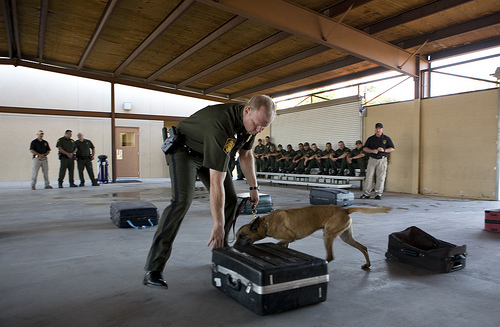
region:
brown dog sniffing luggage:
[249, 212, 365, 270]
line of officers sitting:
[265, 137, 417, 191]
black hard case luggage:
[233, 225, 333, 317]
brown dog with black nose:
[223, 183, 377, 292]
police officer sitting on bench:
[346, 137, 367, 174]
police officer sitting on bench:
[331, 140, 350, 173]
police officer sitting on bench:
[317, 142, 335, 173]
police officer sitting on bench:
[302, 142, 322, 173]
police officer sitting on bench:
[293, 141, 312, 172]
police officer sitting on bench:
[289, 142, 303, 174]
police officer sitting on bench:
[276, 142, 295, 171]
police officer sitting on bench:
[267, 140, 288, 169]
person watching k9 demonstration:
[358, 120, 393, 199]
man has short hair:
[231, 97, 318, 139]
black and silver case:
[203, 262, 335, 323]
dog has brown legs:
[294, 208, 371, 273]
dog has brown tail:
[340, 197, 385, 229]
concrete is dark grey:
[56, 247, 154, 323]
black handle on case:
[208, 262, 274, 317]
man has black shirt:
[186, 112, 238, 153]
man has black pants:
[146, 156, 200, 313]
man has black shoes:
[136, 271, 173, 289]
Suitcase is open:
[386, 212, 472, 277]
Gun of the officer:
[157, 124, 182, 156]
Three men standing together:
[21, 121, 96, 186]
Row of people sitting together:
[279, 136, 350, 171]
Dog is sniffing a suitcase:
[235, 205, 386, 273]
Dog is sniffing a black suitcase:
[229, 202, 384, 309]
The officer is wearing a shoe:
[129, 232, 179, 299]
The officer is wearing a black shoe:
[136, 247, 178, 295]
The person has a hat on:
[368, 120, 386, 140]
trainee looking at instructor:
[352, 138, 368, 174]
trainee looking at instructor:
[334, 138, 349, 167]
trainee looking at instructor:
[320, 137, 333, 168]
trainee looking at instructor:
[310, 140, 321, 166]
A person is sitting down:
[349, 130, 376, 180]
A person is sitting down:
[326, 134, 356, 180]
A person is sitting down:
[310, 130, 335, 174]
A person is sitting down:
[348, 134, 373, 175]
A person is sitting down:
[333, 137, 345, 178]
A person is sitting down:
[321, 137, 338, 165]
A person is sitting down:
[307, 141, 324, 171]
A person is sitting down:
[300, 140, 313, 167]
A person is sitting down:
[293, 140, 306, 172]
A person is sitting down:
[283, 143, 298, 175]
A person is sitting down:
[268, 142, 283, 175]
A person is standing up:
[365, 122, 394, 211]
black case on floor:
[206, 237, 332, 320]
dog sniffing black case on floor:
[205, 199, 396, 320]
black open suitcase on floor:
[383, 221, 472, 274]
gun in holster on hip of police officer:
[158, 121, 183, 157]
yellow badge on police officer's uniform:
[219, 133, 236, 157]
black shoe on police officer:
[140, 265, 171, 292]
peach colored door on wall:
[112, 122, 143, 182]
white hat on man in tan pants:
[33, 126, 48, 137]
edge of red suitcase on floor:
[478, 204, 499, 235]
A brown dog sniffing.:
[233, 202, 394, 272]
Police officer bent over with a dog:
[142, 93, 274, 288]